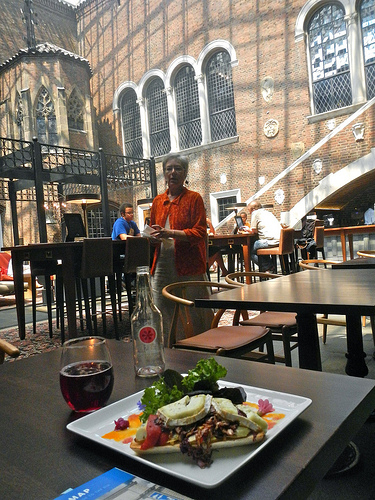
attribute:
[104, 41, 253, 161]
windows — arched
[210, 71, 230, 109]
mesh — metal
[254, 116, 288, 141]
cement brick — round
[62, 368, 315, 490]
plate — square, white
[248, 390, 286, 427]
flower — pink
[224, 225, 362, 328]
table — black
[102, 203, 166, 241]
man — dark-haired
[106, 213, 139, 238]
shirt — short-sleeve, blue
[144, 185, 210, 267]
shirt — orange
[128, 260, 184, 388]
bottle — empty, clear, glass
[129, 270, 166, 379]
bottle — empty